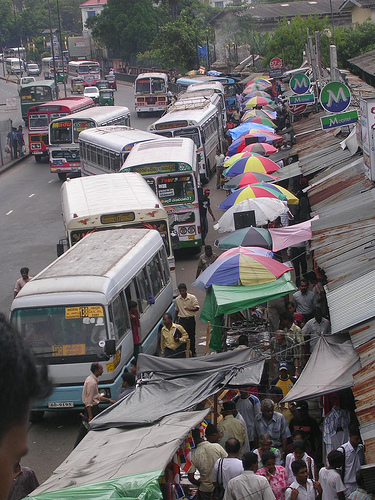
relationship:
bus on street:
[22, 242, 176, 383] [9, 217, 95, 443]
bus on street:
[129, 137, 206, 241] [0, 132, 222, 273]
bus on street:
[49, 104, 128, 177] [0, 61, 373, 499]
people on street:
[291, 279, 319, 321] [0, 61, 373, 499]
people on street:
[215, 148, 225, 188] [0, 61, 373, 499]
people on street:
[287, 397, 322, 467] [0, 61, 373, 499]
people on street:
[73, 360, 113, 446] [0, 61, 373, 499]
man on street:
[172, 282, 200, 358] [0, 61, 373, 499]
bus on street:
[132, 69, 169, 115] [10, 185, 46, 227]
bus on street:
[0, 212, 190, 413] [1, 59, 157, 316]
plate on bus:
[46, 402, 76, 408] [5, 206, 182, 403]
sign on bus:
[99, 212, 134, 227] [59, 168, 180, 293]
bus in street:
[8, 228, 175, 421] [1, 411, 84, 497]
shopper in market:
[283, 458, 325, 498] [193, 74, 371, 497]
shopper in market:
[223, 448, 276, 498] [193, 74, 371, 497]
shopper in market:
[317, 443, 354, 495] [193, 74, 371, 497]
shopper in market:
[192, 418, 229, 488] [193, 74, 371, 497]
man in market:
[254, 398, 292, 464] [193, 74, 371, 497]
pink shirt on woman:
[255, 466, 285, 496] [257, 451, 284, 498]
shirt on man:
[263, 392, 334, 465] [249, 393, 316, 433]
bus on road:
[8, 228, 175, 421] [1, 60, 222, 485]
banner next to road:
[195, 42, 208, 58] [1, 60, 222, 485]